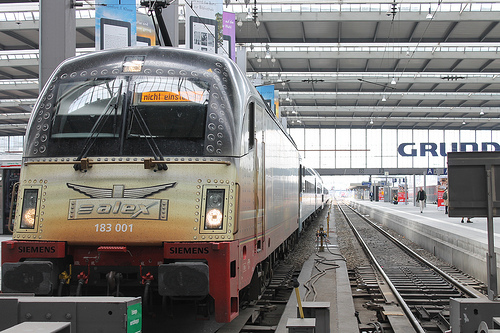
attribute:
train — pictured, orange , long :
[1, 40, 333, 327]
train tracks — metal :
[331, 201, 499, 329]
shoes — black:
[459, 218, 474, 225]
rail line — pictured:
[334, 198, 490, 331]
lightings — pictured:
[277, 40, 374, 50]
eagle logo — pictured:
[63, 178, 176, 198]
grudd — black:
[395, 137, 499, 165]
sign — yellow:
[128, 70, 220, 117]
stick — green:
[126, 303, 143, 330]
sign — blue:
[93, 4, 136, 47]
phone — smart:
[100, 20, 127, 48]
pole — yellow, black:
[290, 282, 306, 319]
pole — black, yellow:
[483, 163, 498, 302]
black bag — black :
[437, 185, 445, 205]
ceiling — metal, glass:
[236, 10, 339, 45]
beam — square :
[39, 0, 74, 94]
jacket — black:
[413, 190, 426, 200]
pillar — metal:
[35, 0, 80, 54]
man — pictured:
[418, 186, 426, 212]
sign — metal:
[443, 149, 498, 219]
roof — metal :
[0, 3, 495, 133]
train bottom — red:
[0, 218, 260, 327]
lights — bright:
[314, 46, 474, 137]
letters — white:
[128, 303, 140, 328]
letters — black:
[140, 92, 189, 101]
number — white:
[91, 219, 112, 232]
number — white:
[110, 223, 136, 233]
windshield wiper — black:
[126, 97, 166, 170]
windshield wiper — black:
[74, 93, 120, 170]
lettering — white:
[128, 304, 140, 329]